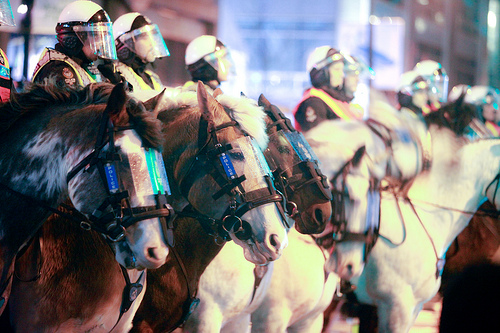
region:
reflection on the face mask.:
[81, 26, 114, 55]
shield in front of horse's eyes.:
[228, 149, 263, 172]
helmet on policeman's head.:
[191, 39, 222, 74]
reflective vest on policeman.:
[322, 97, 349, 114]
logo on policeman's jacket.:
[302, 106, 320, 124]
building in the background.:
[256, 12, 311, 52]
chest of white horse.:
[291, 261, 321, 292]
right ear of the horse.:
[195, 90, 217, 115]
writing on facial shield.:
[99, 164, 120, 190]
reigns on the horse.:
[95, 215, 128, 241]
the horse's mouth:
[100, 226, 190, 288]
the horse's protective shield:
[76, 139, 195, 205]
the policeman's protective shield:
[65, 17, 132, 69]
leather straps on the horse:
[201, 187, 301, 248]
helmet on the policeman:
[296, 34, 376, 102]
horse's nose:
[266, 226, 290, 260]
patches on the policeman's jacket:
[50, 66, 85, 96]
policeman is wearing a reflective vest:
[16, 36, 111, 116]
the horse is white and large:
[231, 104, 391, 328]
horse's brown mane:
[9, 68, 179, 150]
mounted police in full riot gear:
[0, 0, 499, 332]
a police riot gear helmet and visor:
[55, 1, 117, 67]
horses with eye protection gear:
[214, 135, 271, 192]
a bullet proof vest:
[31, 46, 98, 91]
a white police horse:
[383, 138, 499, 332]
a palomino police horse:
[157, 80, 285, 265]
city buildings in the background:
[221, 0, 498, 54]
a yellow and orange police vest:
[1, 46, 12, 103]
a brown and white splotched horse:
[0, 83, 170, 268]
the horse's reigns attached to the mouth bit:
[223, 186, 292, 263]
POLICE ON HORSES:
[36, 0, 301, 309]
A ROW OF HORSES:
[0, 75, 352, 277]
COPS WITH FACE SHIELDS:
[43, 5, 265, 98]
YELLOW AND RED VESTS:
[288, 86, 380, 139]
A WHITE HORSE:
[381, 140, 498, 331]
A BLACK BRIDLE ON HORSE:
[63, 115, 179, 271]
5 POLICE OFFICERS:
[32, 2, 388, 117]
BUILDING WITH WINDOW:
[205, 5, 385, 105]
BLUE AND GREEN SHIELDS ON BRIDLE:
[85, 149, 187, 204]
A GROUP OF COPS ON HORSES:
[293, 40, 494, 161]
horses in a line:
[12, 2, 453, 330]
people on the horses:
[18, 7, 499, 307]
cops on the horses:
[15, 13, 494, 299]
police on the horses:
[22, 10, 474, 304]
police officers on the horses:
[30, 2, 482, 285]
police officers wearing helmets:
[53, 0, 264, 123]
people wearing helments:
[54, 2, 289, 107]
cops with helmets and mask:
[54, 23, 296, 107]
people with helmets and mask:
[35, 13, 251, 120]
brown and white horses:
[54, 38, 496, 323]